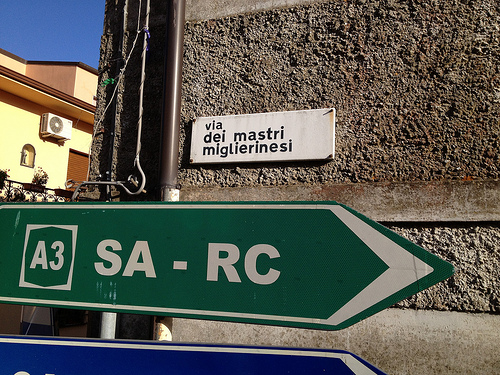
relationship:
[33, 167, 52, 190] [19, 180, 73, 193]
plant in planter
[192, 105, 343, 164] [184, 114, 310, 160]
white sign words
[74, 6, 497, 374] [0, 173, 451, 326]
wall with sign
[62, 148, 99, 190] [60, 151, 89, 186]
wooden door slats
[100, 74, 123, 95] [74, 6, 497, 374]
green ties wall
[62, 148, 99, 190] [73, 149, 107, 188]
part of door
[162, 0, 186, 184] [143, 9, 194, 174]
brown on pipe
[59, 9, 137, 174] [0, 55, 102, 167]
brown on building